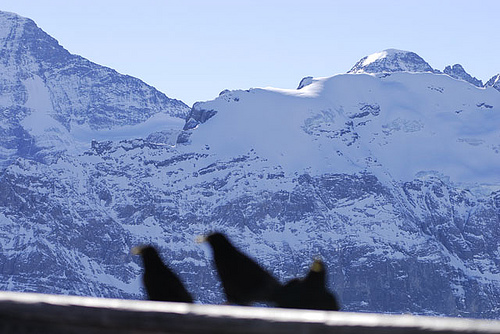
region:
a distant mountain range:
[0, 10, 499, 319]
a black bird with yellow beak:
[131, 243, 193, 303]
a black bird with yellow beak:
[193, 231, 310, 309]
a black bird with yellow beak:
[283, 259, 338, 310]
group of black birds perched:
[123, 228, 340, 315]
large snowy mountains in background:
[1, 13, 496, 300]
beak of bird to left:
[130, 242, 141, 254]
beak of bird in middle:
[193, 231, 206, 246]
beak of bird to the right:
[306, 255, 324, 272]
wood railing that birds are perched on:
[2, 288, 498, 331]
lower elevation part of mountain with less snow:
[330, 250, 457, 310]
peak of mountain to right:
[348, 46, 427, 79]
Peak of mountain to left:
[4, 10, 46, 55]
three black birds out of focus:
[120, 225, 373, 323]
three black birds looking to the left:
[128, 233, 370, 313]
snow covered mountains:
[0, 10, 493, 326]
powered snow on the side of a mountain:
[208, 71, 488, 187]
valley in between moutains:
[21, 85, 208, 150]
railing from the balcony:
[5, 287, 487, 329]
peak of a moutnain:
[346, 42, 432, 68]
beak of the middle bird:
[190, 233, 206, 243]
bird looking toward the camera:
[280, 258, 360, 298]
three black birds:
[121, 232, 357, 312]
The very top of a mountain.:
[167, 29, 499, 137]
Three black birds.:
[116, 195, 362, 319]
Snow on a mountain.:
[237, 102, 299, 143]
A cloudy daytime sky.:
[98, 5, 318, 57]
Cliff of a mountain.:
[60, 140, 499, 264]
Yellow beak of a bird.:
[192, 222, 206, 247]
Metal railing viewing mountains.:
[7, 281, 494, 331]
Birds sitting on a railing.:
[133, 208, 381, 321]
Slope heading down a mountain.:
[66, 93, 224, 158]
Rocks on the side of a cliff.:
[335, 163, 487, 298]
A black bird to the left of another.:
[129, 244, 192, 302]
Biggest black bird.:
[199, 230, 289, 305]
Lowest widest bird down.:
[282, 258, 337, 312]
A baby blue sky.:
[0, 0, 498, 105]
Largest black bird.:
[196, 232, 284, 308]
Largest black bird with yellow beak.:
[197, 232, 297, 311]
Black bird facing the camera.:
[282, 261, 337, 313]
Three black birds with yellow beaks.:
[130, 231, 337, 313]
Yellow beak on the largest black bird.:
[194, 237, 206, 244]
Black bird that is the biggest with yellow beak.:
[197, 232, 282, 306]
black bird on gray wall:
[185, 219, 274, 314]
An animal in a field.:
[118, 222, 188, 325]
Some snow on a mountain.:
[350, 77, 426, 180]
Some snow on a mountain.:
[408, 70, 474, 144]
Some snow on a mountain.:
[33, 104, 223, 131]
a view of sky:
[188, 33, 246, 77]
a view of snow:
[173, 87, 269, 158]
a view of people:
[187, 205, 309, 303]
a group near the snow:
[140, 253, 285, 303]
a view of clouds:
[281, 29, 335, 59]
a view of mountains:
[122, 63, 344, 173]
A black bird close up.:
[270, 265, 332, 315]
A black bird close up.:
[132, 233, 178, 292]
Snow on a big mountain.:
[225, 87, 308, 153]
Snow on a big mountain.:
[385, 126, 443, 167]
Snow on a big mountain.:
[391, 73, 458, 113]